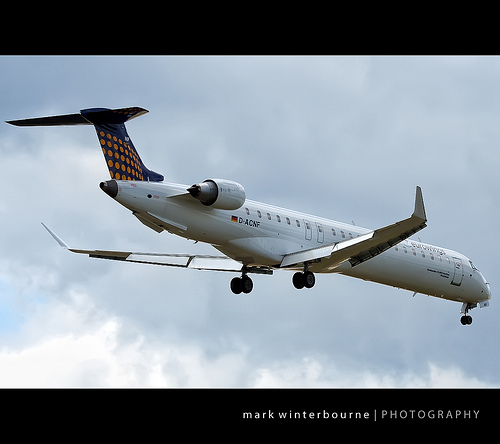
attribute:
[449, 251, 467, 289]
door — emergency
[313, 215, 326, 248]
door — emergency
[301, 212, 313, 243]
door — emergency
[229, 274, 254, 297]
wheels — out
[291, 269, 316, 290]
wheels — out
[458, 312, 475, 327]
wheels — out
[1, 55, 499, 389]
sky — blue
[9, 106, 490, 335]
plane — WHITE, blue, orange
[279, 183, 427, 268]
wing — long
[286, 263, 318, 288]
wheels — ready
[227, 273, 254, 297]
wheels — ready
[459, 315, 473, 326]
wheels — ready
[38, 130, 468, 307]
airplane — white